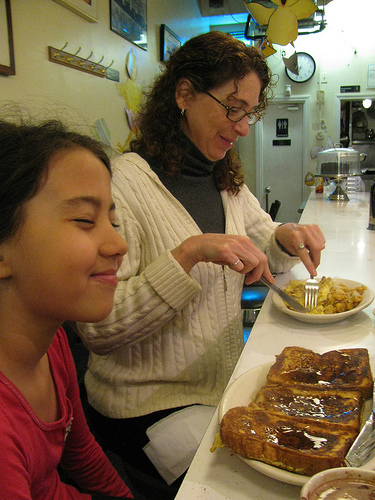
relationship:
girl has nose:
[9, 130, 126, 415] [93, 229, 125, 258]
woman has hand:
[150, 29, 294, 294] [177, 243, 279, 293]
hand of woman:
[272, 217, 332, 269] [150, 29, 294, 294]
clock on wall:
[279, 50, 315, 86] [73, 7, 369, 82]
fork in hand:
[303, 264, 323, 304] [272, 217, 332, 269]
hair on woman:
[167, 31, 242, 80] [150, 29, 294, 294]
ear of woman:
[171, 77, 194, 111] [150, 29, 294, 294]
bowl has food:
[262, 290, 369, 331] [310, 303, 324, 315]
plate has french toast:
[226, 383, 324, 485] [277, 354, 349, 447]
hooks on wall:
[48, 42, 136, 71] [73, 7, 369, 82]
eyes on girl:
[55, 209, 140, 239] [9, 130, 126, 415]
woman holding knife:
[150, 29, 294, 294] [251, 273, 313, 313]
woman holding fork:
[150, 29, 294, 294] [303, 264, 323, 304]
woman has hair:
[150, 29, 294, 294] [167, 31, 242, 80]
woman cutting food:
[150, 29, 294, 294] [290, 283, 360, 319]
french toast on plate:
[277, 354, 349, 447] [226, 383, 324, 485]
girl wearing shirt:
[9, 130, 126, 415] [0, 405, 110, 491]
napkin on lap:
[153, 414, 200, 470] [128, 392, 219, 465]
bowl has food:
[262, 290, 369, 331] [290, 283, 360, 319]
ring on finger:
[289, 238, 310, 251] [291, 239, 316, 277]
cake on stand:
[318, 159, 359, 177] [319, 149, 362, 207]